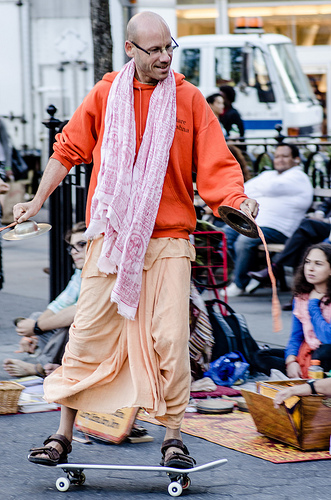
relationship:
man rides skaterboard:
[11, 10, 248, 463] [28, 457, 227, 495]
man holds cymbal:
[11, 10, 248, 463] [218, 203, 260, 239]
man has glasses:
[6, 219, 93, 381] [65, 240, 87, 254]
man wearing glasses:
[11, 10, 248, 463] [127, 37, 180, 58]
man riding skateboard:
[11, 10, 248, 463] [28, 457, 227, 495]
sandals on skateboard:
[26, 432, 194, 470] [28, 457, 227, 495]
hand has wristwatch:
[273, 376, 331, 405] [305, 377, 317, 397]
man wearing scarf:
[11, 10, 248, 463] [82, 56, 177, 318]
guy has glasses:
[11, 10, 248, 463] [127, 37, 180, 58]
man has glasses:
[11, 10, 248, 463] [127, 37, 180, 58]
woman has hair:
[253, 239, 330, 379] [291, 241, 330, 297]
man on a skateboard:
[11, 10, 248, 463] [28, 457, 227, 495]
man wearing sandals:
[11, 10, 248, 463] [26, 432, 194, 470]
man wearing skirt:
[11, 10, 248, 463] [40, 231, 199, 432]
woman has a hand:
[253, 239, 330, 379] [307, 288, 324, 302]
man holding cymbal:
[11, 10, 248, 463] [218, 203, 260, 239]